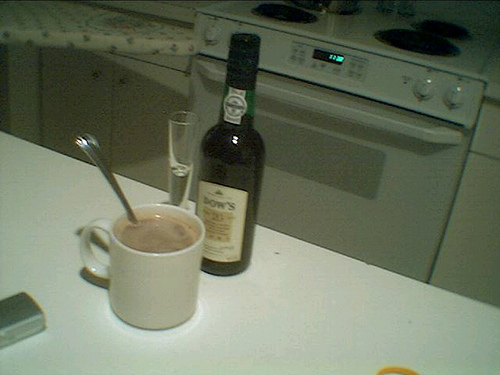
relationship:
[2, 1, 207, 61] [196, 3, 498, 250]
ironing board next to stove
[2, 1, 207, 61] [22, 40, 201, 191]
ironing board by cabinet